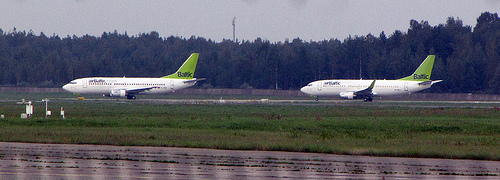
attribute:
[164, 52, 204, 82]
tail — green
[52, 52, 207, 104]
airplane — large, white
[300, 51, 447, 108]
airplane — white, large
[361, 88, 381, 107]
motorcycle — red, black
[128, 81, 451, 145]
grass — green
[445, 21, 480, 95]
tree — tall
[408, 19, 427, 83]
tree — tall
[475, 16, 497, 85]
tree — tall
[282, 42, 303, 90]
tree — tall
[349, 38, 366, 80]
tree — tall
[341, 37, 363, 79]
tree — tall, leafy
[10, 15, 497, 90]
trees — large, green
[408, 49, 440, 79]
tail — yellow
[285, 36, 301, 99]
tree — tall, leafy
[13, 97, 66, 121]
devices — white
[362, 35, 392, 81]
tree — tall, green, leafy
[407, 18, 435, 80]
tree — leafy, tall, green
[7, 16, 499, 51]
trees — forest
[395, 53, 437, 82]
tail — green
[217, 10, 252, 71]
flag pole — large, tall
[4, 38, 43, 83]
tree — green, tall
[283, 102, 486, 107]
asphalt — large, grey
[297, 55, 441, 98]
airplane — white